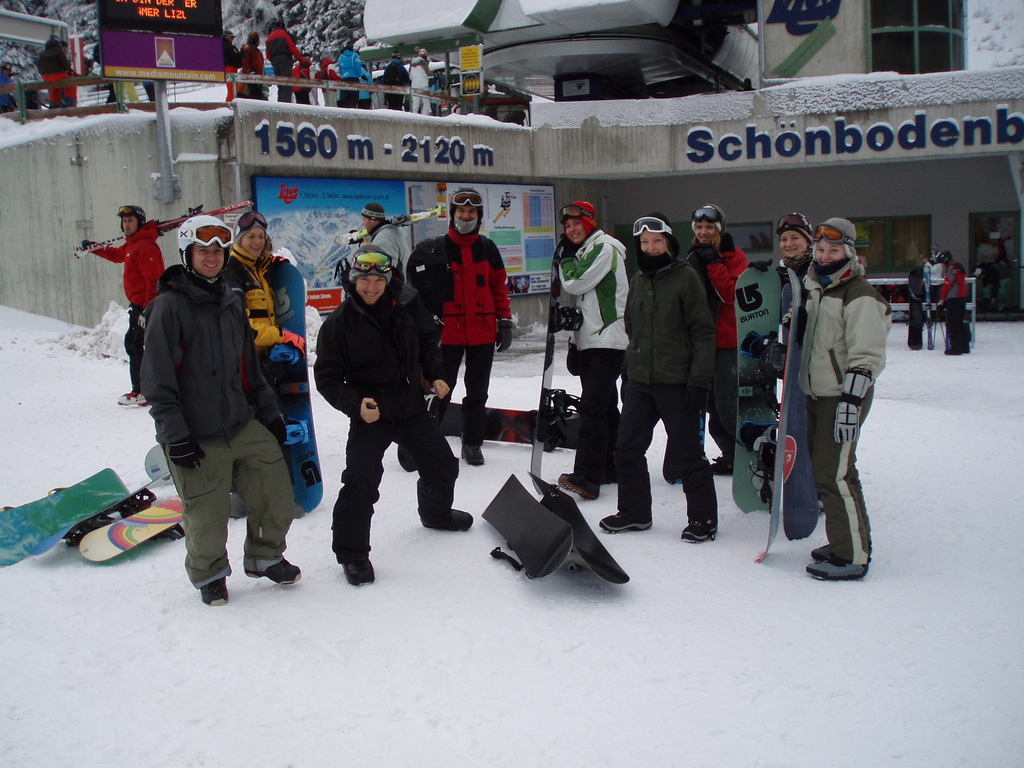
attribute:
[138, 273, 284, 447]
jacket — grey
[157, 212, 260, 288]
helmet — white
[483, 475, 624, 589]
snowboards — black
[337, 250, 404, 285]
ski goggles — yellow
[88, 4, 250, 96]
digital display — ski conditions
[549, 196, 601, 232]
cap — red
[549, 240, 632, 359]
jacket — white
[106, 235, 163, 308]
jacket — red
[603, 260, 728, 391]
jacket — grey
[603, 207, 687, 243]
ski goggles — white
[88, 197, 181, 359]
jacket — red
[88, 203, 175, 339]
jacket — red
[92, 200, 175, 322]
jacket — red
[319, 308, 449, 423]
jacket — black 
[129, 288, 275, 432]
jacket — black